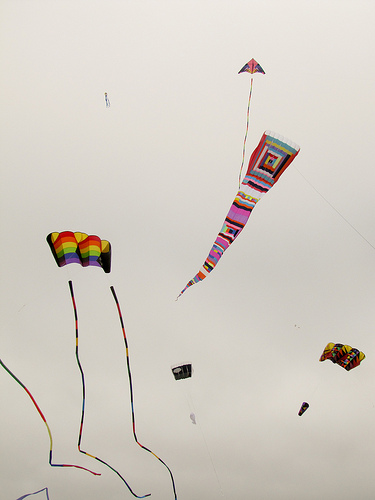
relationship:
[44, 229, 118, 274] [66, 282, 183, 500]
kite have two tails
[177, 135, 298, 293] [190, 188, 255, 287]
kite change color in lines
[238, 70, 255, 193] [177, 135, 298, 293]
strings are connected to kite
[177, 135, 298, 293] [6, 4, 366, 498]
kite on air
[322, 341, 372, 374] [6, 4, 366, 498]
kite on air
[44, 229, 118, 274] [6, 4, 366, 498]
kite on air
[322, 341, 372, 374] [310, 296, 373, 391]
kite on right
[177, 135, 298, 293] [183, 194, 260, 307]
kite have tail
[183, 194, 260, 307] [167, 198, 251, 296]
tail have a pattern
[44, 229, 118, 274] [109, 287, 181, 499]
kite have tail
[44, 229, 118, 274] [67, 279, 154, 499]
kite have tail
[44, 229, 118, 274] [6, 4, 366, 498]
kite in sky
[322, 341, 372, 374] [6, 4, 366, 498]
kite on sky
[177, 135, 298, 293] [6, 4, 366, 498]
kite on sky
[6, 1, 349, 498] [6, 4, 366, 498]
clouds are in sky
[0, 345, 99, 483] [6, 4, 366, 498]
ribbon in sky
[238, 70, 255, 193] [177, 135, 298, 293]
strings on kite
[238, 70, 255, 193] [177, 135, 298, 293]
string on kite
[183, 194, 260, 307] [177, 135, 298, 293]
tail on kite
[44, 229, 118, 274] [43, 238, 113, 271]
kite have stripes